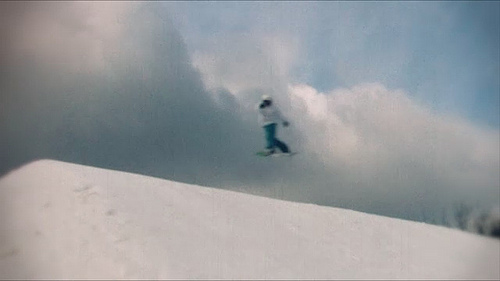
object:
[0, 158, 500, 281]
slope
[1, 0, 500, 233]
sky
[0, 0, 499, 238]
cloud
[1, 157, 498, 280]
mountain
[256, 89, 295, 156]
man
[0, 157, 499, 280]
ground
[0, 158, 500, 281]
snow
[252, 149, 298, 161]
snowboard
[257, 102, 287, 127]
hoodie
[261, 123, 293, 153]
pants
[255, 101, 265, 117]
arm